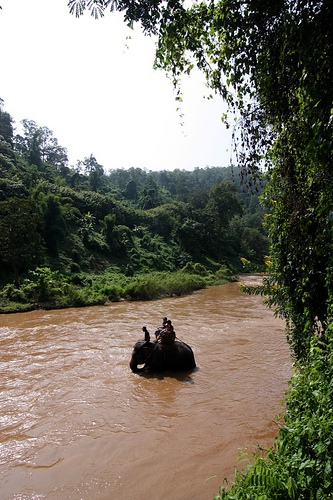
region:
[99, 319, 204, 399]
a elephant in the water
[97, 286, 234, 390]
a elephant in the water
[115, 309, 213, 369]
a elephant in the water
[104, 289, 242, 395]
elephant in the river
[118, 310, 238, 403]
people riding on the elephant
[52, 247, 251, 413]
muddy river with people crossing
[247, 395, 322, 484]
foliage along the river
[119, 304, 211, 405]
Elephant crossing river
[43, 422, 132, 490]
muddy water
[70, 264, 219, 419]
River with muddy water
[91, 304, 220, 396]
Traveling in the jungle on an elephant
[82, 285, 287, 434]
On a tour of the forrest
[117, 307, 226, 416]
Elephant carrying people across the river.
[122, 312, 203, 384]
people on the back of an elephant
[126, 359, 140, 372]
the trunk of an elephant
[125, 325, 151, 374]
a man on the neck of an elephant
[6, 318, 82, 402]
the moving water of a river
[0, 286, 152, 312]
the bank of a river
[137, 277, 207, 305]
the bank of a river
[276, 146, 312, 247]
the leaves of a tree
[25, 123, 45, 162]
the leaves of a tree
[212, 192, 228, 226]
the leaves of a tree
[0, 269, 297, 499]
Water covering the surface.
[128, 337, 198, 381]
gray color on the elephant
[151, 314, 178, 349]
People riding the elephant.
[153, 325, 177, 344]
Basket carrier on the elephant.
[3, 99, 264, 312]
Trees in the background.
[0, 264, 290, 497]
Brown color of the water.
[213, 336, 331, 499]
Green plants on the bank.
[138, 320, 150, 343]
Man walking beside the elephant.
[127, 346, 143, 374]
Trunk on the elephant.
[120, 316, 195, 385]
dark elephant in water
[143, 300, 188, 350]
people riding on elephant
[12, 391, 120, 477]
water is dark brown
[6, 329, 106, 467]
large current on water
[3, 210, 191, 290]
green trees on hill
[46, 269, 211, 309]
green bushes near shore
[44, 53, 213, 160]
grey and white sky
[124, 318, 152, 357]
person sitting on elephant's head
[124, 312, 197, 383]
gray elephant carrying people in water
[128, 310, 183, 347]
people riding on elephant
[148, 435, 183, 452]
ripples in brown river water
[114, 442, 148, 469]
ripples in brown river water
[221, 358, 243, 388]
ripples in brown river water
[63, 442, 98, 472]
ripples in brown river water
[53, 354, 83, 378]
ripples in brown river water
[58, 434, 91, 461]
ripples in brown river water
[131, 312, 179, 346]
people on top of elephant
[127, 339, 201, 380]
gray elephant in river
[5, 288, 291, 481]
brown flowing river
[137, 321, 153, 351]
man on front of elephant head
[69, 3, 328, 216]
vines hanging over river